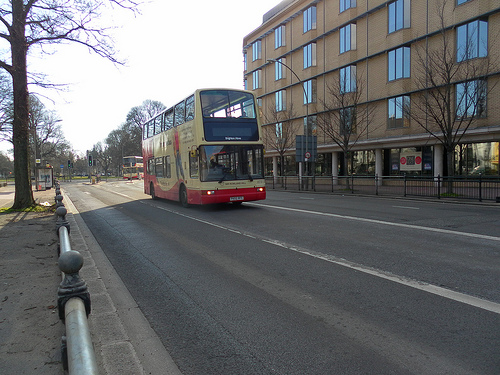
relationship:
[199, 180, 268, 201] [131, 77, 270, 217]
headlights of bus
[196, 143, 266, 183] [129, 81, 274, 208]
window on bus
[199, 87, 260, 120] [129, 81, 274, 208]
window on bus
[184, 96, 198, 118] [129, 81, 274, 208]
window on bus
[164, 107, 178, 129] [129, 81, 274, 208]
window on bus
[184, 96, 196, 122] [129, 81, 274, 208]
window on bus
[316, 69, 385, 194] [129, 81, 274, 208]
tree behind bus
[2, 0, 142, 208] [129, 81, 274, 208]
tree behind bus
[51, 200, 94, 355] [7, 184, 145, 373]
rail on sidewalk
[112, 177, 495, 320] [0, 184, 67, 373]
line on sidewalk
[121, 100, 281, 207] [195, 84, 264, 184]
bus has front view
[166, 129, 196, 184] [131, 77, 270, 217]
ad on bus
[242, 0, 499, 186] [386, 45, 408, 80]
building has window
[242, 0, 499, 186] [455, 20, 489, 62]
building has window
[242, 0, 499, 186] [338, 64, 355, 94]
building has window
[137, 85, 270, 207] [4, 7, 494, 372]
photo in ohio